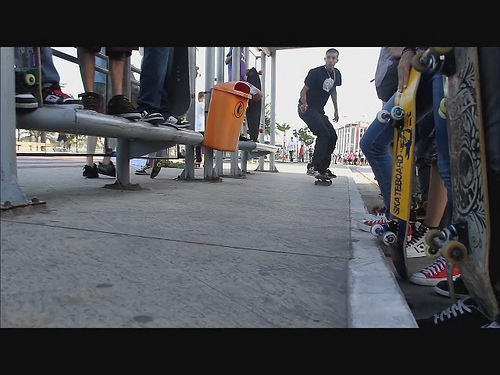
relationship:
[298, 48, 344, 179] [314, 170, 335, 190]
man riding skateboard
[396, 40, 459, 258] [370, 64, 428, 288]
boy holding skateboard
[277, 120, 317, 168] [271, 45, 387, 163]
trees in distance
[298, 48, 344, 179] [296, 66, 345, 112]
man wearing shirt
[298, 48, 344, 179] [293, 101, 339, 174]
man wearing pants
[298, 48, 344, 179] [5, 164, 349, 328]
man riding down sidewalk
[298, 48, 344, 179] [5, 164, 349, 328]
man down sidewalk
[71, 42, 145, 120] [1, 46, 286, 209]
person on railing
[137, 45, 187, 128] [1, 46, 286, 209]
person on railing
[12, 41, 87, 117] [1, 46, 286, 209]
person on railing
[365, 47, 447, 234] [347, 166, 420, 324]
person along curb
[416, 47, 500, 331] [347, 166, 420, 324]
person along curb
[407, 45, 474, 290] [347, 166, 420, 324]
person along curb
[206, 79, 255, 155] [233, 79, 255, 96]
can with opening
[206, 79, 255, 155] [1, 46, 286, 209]
can hanging from railing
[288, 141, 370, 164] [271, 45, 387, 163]
pedestrians in background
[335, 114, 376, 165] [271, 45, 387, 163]
building in background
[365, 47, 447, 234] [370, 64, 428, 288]
person holding skateboard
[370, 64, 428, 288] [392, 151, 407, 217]
skateboard says skateboard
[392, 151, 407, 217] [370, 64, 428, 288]
skateboard on skateboard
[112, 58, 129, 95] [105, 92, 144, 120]
leg on shoe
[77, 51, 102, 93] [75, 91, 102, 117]
leg on shoe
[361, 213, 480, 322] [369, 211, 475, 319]
sneakers with laces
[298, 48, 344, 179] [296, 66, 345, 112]
man in shirt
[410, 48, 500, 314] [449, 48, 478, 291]
skateboard with drawing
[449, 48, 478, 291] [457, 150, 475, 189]
drawing includes circles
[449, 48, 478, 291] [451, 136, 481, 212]
drawing includes circles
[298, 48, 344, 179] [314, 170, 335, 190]
boy riding skateboard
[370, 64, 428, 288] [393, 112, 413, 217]
skateboard with logo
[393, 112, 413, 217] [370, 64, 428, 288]
logo on skateboard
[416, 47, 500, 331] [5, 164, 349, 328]
skateboarder along sidewalk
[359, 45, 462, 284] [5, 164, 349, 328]
person along sidewalk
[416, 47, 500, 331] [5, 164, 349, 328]
person along sidewalk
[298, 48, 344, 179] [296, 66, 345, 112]
boy wearing shirt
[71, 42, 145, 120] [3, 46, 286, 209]
person on bench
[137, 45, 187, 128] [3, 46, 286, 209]
person on bench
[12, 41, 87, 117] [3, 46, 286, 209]
person on bench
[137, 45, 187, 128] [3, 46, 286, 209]
person standing on bench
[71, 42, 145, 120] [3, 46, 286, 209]
person standing on bench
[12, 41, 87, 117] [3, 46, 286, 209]
person standing on bench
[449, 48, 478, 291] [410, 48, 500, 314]
drawing on skateboard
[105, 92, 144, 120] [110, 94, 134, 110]
shoe with laces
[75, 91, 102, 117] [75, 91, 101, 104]
shoe with laces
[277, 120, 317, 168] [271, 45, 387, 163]
trees in background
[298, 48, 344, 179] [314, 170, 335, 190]
man on skateboard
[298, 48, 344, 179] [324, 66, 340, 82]
man has chain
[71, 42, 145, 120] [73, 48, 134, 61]
person wearing shorts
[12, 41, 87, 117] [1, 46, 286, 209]
skater standing on platform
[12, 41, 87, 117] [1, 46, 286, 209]
skater on platform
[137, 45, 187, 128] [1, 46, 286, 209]
skater on platform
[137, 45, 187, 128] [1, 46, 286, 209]
skater standing on platform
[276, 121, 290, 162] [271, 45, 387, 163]
tree in background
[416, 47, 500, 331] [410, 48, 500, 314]
boy holding skateboard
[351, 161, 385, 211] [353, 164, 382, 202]
street with stripe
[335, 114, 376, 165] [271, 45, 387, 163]
building in back